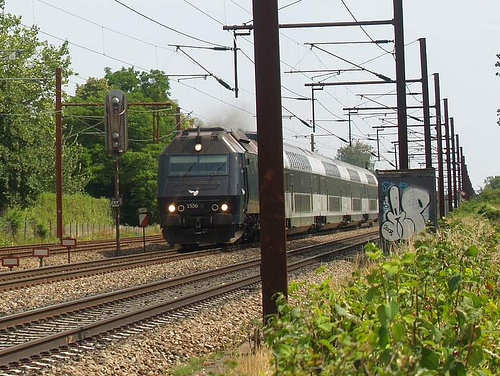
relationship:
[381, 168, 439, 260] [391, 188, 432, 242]
graffiti on sign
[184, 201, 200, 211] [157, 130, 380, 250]
1536 on train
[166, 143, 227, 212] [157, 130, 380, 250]
headlights on train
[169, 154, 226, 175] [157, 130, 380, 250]
winshield on train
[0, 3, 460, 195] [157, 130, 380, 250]
power lines above train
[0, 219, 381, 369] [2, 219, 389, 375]
train tracks on gravel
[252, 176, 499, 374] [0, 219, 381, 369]
green plants by train tracks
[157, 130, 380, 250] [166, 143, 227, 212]
train has headlights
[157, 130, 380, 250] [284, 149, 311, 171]
train has windows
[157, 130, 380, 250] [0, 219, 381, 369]
train on train tracks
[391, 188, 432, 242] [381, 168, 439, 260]
sign has graffiti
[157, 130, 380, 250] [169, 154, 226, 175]
train has a windows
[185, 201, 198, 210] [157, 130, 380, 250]
number on train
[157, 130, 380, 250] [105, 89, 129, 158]
train has train signal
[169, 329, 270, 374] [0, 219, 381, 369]
grass near train tracks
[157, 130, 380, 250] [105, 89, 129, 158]
train near train signal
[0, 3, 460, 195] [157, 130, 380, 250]
power lines run train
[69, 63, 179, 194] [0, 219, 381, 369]
tree near train tracks